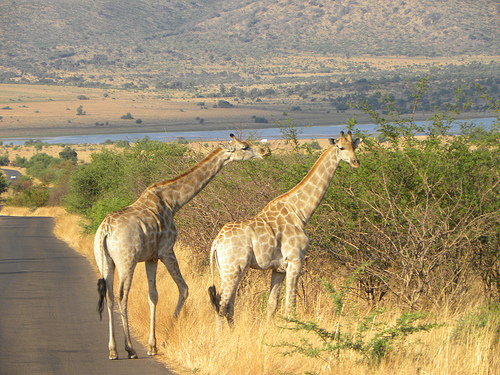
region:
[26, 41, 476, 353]
The giraffes are slowly walking around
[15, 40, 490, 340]
The giraffes are close to the road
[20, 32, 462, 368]
The giraffes are on a highway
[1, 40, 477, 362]
The giraffes are looking for food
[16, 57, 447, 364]
The giraffes are male and female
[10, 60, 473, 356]
The giraffes are close to the bushes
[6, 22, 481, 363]
The giraffes are looking for adventure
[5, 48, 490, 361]
The giraffes are out in the daytime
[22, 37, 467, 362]
The giraffes are enjoying the day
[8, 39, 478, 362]
The giraffes are avoiding the traffic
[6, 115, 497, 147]
blue water of a river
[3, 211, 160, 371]
a paved road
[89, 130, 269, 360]
a giraffe walking towards the yellow grass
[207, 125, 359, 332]
giraffe is standing in dried grass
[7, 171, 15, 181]
vehicle on the road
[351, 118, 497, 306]
green bushes with brown stems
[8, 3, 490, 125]
tall hills above river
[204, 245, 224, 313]
giraffe tail hanging down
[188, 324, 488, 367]
dried grass and small green bush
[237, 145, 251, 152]
eye of a giraffe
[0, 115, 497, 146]
Water in the distance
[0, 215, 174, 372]
A road by the giraffes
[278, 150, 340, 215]
The giraffe has a long neck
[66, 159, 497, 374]
Bushes near the giraffes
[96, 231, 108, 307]
The tail of the giraffe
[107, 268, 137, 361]
The legs of the giraffe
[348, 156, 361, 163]
The nose of the giraffe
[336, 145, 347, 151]
The right eye of the giraffe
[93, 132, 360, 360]
Two giraffes by the road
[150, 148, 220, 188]
The mane of the giraffe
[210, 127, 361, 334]
giraffe is next to giraffe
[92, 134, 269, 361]
giraffe is next to giraffe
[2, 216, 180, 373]
giraffe is standing on road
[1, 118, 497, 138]
body of water is blue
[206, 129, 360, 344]
giraffe is standing on dry grass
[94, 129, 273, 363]
giraffe behind another giraffe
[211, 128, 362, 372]
giraffe in front of giraffe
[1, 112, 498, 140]
water is behind giraffe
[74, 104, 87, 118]
bush is planted on dirt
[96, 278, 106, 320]
giraffe has tail with black tip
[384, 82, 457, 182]
Bright Green tree top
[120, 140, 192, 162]
Bright Green tree top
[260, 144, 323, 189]
Bright Green tree top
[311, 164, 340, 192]
Brown spots on an animal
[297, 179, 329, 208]
Brown spots on an animal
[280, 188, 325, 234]
Brown spots on an animal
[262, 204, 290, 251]
Brown spots on an animal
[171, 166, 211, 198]
Brown spots on an animal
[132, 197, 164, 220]
Brown spots on an animal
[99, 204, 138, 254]
Brown spots on an animal